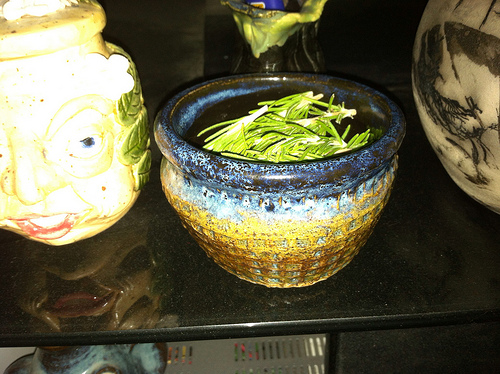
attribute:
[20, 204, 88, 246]
lips — red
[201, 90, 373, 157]
needles — green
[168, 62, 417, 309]
bowl — textured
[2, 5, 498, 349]
black table — Reflective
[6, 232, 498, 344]
table — reflective, black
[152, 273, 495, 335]
table — black, Reflective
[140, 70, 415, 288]
bowl — blue, yellow, and brown, inside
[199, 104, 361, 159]
pine needles — small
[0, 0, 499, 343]
shelf — glass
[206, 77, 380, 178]
rosemary — green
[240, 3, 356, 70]
leaf — ceramic, green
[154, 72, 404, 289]
bowl — ceramic